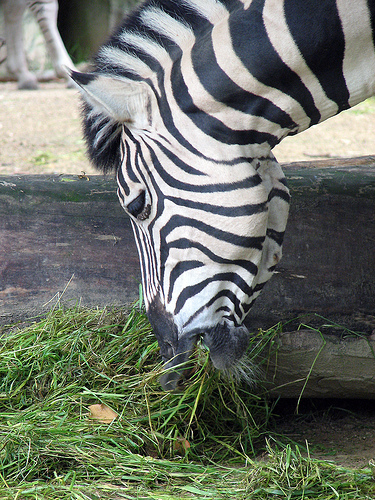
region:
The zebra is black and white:
[67, 17, 355, 384]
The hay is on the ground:
[15, 300, 342, 489]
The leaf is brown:
[78, 396, 138, 427]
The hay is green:
[16, 298, 326, 495]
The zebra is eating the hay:
[82, 15, 364, 373]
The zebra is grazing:
[79, 3, 359, 381]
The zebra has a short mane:
[67, 4, 240, 165]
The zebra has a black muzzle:
[141, 299, 250, 387]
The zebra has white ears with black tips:
[64, 57, 139, 115]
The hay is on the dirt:
[15, 297, 242, 492]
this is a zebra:
[73, 24, 368, 199]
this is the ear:
[62, 61, 137, 126]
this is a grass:
[54, 389, 142, 447]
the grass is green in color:
[17, 405, 62, 454]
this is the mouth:
[164, 289, 239, 384]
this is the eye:
[122, 193, 146, 218]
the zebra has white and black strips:
[174, 188, 235, 238]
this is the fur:
[113, 25, 173, 66]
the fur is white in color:
[238, 360, 250, 381]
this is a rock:
[315, 209, 373, 385]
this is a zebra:
[27, 1, 369, 304]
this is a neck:
[202, 2, 357, 103]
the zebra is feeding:
[155, 327, 250, 405]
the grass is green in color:
[0, 330, 137, 413]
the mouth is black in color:
[215, 326, 236, 363]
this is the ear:
[68, 57, 125, 132]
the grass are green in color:
[17, 325, 147, 481]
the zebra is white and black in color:
[181, 148, 236, 238]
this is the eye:
[129, 198, 141, 210]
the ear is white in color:
[99, 81, 129, 106]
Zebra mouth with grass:
[147, 330, 253, 407]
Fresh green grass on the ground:
[0, 309, 371, 495]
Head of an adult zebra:
[60, 60, 307, 397]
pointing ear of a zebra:
[55, 59, 158, 132]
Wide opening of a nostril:
[154, 340, 177, 364]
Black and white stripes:
[161, 134, 236, 269]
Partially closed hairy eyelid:
[120, 182, 156, 223]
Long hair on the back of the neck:
[62, 0, 230, 83]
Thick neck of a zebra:
[183, 0, 371, 153]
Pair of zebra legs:
[1, 0, 78, 93]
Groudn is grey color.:
[27, 107, 89, 253]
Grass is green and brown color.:
[22, 367, 151, 471]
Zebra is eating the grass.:
[93, 221, 284, 410]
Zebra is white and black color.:
[159, 55, 291, 244]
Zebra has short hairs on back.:
[112, 22, 188, 64]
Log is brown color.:
[291, 330, 359, 385]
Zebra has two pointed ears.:
[46, 50, 187, 140]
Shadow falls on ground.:
[20, 133, 106, 238]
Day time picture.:
[14, 24, 335, 466]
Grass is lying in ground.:
[16, 314, 256, 425]